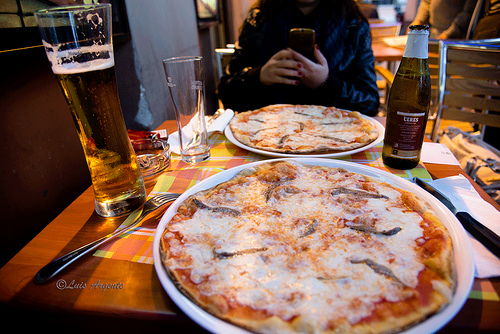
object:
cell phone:
[288, 27, 315, 63]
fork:
[31, 192, 180, 285]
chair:
[427, 40, 499, 142]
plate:
[223, 105, 386, 157]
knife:
[411, 176, 499, 258]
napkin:
[423, 173, 499, 278]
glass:
[32, 2, 145, 216]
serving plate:
[152, 156, 474, 333]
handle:
[455, 211, 499, 253]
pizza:
[229, 103, 380, 154]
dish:
[151, 157, 476, 333]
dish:
[223, 104, 384, 157]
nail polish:
[296, 62, 301, 67]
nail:
[294, 63, 301, 67]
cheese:
[184, 172, 422, 322]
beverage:
[53, 64, 142, 201]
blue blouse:
[217, 2, 380, 117]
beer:
[54, 65, 139, 200]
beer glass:
[160, 55, 211, 163]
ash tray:
[130, 138, 171, 176]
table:
[0, 118, 498, 333]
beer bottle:
[380, 24, 430, 170]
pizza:
[159, 160, 455, 333]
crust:
[427, 218, 454, 303]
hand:
[260, 50, 302, 85]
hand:
[287, 43, 329, 85]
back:
[0, 48, 94, 265]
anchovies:
[364, 258, 399, 281]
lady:
[216, 0, 379, 116]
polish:
[296, 72, 304, 75]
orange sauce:
[371, 302, 410, 319]